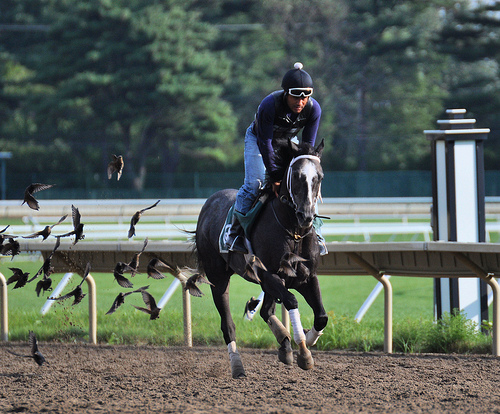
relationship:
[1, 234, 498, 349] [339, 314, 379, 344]
railing over surfaces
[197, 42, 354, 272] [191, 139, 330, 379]
jockey riding horse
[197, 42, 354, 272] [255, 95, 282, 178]
jockey supported by arm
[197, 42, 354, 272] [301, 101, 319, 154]
jockey supported by arm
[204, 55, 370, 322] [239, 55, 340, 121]
man wearing helmet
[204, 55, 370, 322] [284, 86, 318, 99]
man wearing goggles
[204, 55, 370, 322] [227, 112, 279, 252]
man wearing pants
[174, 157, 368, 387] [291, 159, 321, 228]
horse has face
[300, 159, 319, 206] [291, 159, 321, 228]
stripe on face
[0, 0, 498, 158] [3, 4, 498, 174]
leaves on trees